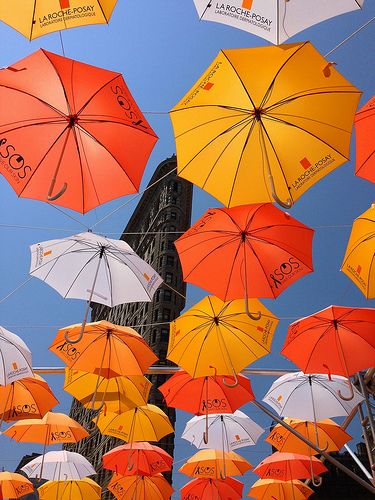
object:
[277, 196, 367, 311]
sky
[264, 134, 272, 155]
ground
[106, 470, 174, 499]
umbrella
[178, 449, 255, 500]
umbrella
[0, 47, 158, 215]
umbrella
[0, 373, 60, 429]
umbrella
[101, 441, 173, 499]
umbrella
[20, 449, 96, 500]
umbrella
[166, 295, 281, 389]
umbrella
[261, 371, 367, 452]
umbrella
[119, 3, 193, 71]
bright sky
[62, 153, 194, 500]
building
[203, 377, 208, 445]
bars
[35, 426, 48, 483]
bars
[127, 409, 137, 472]
bars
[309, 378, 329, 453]
bars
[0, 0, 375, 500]
picture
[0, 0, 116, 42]
umbrella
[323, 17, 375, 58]
wires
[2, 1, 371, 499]
air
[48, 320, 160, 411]
umbrella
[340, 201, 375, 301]
umbrella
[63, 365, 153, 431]
umbrella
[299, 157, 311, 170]
logo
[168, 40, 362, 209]
umbrella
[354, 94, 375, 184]
umbrella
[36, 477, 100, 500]
umbrella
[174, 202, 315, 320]
umbrella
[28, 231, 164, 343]
umbrella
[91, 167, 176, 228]
wire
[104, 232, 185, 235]
wire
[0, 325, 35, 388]
umbrella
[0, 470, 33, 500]
umbrella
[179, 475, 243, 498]
umbrella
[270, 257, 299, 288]
awareness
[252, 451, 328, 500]
umbrella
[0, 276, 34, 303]
wire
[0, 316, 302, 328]
wire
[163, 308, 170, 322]
window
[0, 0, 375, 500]
cables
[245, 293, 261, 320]
handle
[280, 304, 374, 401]
umbrella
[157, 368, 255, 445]
umbrella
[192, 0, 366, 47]
umbrella